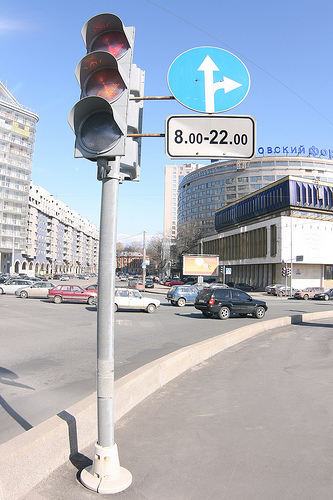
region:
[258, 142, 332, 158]
Letters are blue color.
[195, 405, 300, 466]
Road is grey color.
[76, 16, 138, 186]
Traffic light is attached to the pole.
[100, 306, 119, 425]
Pole is grey color.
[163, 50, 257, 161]
Sign boards are attached to the pole.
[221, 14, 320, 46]
Sky is blue color.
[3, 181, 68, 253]
Windows are attached to the building wall.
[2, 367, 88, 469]
Shadow falls on the road.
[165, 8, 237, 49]
Power lines are passing across the road.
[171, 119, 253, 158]
8.00-22.00 is written in the white board.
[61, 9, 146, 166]
A Traffic Light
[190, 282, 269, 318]
A Black SUV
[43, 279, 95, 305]
A Red Car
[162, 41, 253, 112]
A Traffic Control Sign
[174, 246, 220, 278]
A Billboard advertising products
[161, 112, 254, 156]
A Sign listing specific times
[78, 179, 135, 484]
A Pole in the street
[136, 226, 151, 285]
A Utility Pole for holding up traffic information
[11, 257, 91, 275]
Arches in a building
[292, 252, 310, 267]
A Traffic Sign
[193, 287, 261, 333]
the black parked suv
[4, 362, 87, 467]
shadow of the light pole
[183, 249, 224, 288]
the orange short billboard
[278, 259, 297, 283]
street lights to the right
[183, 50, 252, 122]
white arrows on the green sign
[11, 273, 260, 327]
parking lot full of cars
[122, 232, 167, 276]
trees in the far off distance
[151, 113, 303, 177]
sign that has the numbers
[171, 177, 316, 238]
the round corporate building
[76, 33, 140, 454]
the streetlight in front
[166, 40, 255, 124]
Green and white sign.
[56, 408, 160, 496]
White base of a light pole.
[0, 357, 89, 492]
Shadow on the cement.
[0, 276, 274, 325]
Cars in a parking lot.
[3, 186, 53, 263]
Building with a balcony.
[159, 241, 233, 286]
Billboard beside a building.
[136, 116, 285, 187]
Black and white sign.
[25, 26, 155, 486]
Street lights on a silver pole.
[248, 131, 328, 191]
Blue letters on top of building.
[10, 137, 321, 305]
Buildings and parked cars.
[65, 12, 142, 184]
A gray traffic light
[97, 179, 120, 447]
Tall gray silver metal pole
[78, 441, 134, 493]
wide and flat base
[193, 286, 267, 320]
A black SUV wagon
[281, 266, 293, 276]
Three gray traffic lights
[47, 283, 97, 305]
A red and white compact car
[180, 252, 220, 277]
Black, orange and white sign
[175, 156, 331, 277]
A huge round building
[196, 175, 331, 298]
Blue and white square building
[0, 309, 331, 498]
White and gray concrete curve